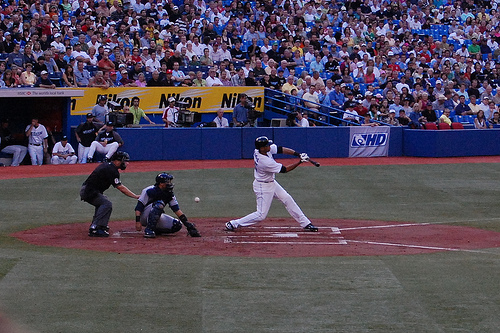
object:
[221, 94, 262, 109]
nikon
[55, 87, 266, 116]
banner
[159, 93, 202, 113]
nikon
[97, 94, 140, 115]
nikon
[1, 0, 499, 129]
stands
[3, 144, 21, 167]
legs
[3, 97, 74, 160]
dugout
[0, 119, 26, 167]
man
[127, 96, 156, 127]
man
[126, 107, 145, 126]
shirt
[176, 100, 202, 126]
video camera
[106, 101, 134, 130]
video camera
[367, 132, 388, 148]
hd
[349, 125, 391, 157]
banner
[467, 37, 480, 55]
man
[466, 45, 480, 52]
shirt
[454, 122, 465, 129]
seat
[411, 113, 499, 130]
front row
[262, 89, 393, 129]
rails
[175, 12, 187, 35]
person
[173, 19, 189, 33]
outfit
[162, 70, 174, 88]
person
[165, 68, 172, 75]
baseball cap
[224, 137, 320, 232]
baseball player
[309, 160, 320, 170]
bat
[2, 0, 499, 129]
spectators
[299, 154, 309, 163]
hands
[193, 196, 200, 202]
baseball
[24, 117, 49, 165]
player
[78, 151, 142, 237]
umpire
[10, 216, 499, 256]
dirt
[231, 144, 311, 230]
uniform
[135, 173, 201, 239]
catcher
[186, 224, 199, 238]
mitt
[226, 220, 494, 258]
lines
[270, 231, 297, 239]
homeplate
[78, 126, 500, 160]
wall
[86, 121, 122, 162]
players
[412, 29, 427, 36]
seat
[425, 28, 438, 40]
seat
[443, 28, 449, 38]
seat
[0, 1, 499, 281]
stadium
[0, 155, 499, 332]
baseball game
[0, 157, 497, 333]
field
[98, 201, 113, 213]
knees